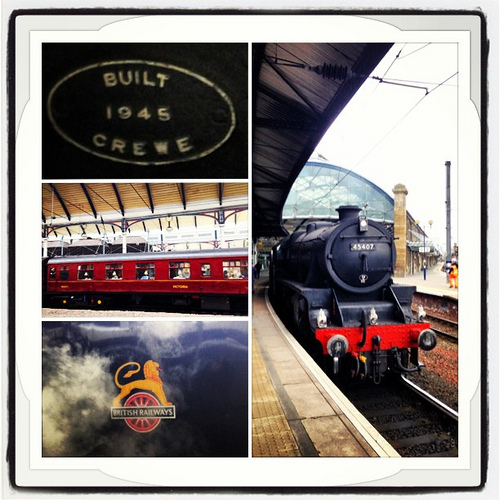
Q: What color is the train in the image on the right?
A: Black.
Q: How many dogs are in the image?
A: 0.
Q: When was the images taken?
A: Daytime.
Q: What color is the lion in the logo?
A: Gold.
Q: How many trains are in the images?
A: 2.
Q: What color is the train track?
A: Silver.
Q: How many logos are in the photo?
A: 2.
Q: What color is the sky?
A: Blue.